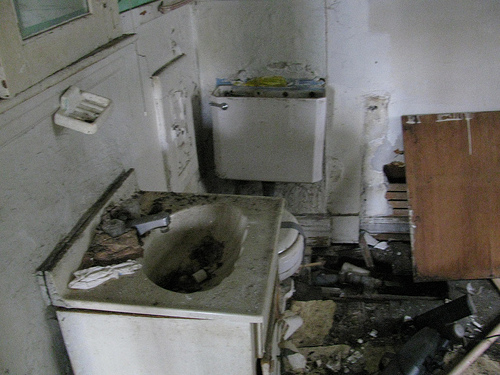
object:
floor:
[285, 240, 500, 375]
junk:
[284, 227, 500, 375]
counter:
[43, 167, 286, 323]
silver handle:
[209, 102, 228, 110]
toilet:
[209, 85, 327, 196]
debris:
[278, 278, 351, 375]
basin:
[44, 167, 286, 375]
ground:
[328, 172, 363, 197]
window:
[0, 0, 124, 102]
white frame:
[0, 0, 193, 100]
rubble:
[356, 330, 381, 344]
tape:
[280, 221, 306, 265]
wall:
[389, 77, 499, 111]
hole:
[382, 164, 406, 184]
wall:
[191, 0, 500, 60]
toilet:
[277, 210, 305, 281]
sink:
[140, 202, 248, 295]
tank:
[208, 85, 327, 184]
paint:
[50, 296, 268, 375]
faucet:
[101, 212, 170, 237]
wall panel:
[152, 52, 199, 192]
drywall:
[327, 60, 389, 156]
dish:
[53, 85, 114, 134]